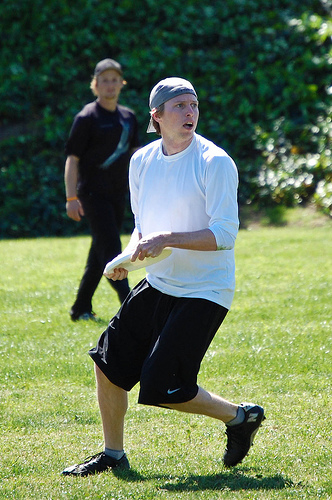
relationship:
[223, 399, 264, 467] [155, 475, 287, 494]
shoe has shadow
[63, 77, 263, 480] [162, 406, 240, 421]
male has shin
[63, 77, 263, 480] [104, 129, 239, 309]
male has shirt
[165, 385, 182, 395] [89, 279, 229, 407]
nike swoosh on top of shorts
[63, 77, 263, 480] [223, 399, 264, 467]
male has shoe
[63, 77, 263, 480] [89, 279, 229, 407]
male has shorts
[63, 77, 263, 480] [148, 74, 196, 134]
male has hat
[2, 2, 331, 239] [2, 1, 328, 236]
tree has foliage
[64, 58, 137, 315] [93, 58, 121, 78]
player has cap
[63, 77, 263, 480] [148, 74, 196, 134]
male wearing hat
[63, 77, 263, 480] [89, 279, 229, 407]
male wearing shorts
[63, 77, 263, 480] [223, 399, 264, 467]
male wearing shoe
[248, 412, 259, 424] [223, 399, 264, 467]
sign on top of shoe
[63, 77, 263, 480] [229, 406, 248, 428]
male wearing sock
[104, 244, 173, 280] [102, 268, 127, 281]
frisbee inside of hand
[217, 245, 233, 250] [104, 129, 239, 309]
stain on top of shirt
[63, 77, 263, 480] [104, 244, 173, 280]
male throwing frisbee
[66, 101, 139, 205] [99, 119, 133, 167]
shirt has design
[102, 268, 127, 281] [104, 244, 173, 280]
hand holding frisbee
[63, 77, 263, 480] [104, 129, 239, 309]
male wearing shirt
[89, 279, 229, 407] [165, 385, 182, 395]
shorts have nike swoosh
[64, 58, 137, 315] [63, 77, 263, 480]
player behind male